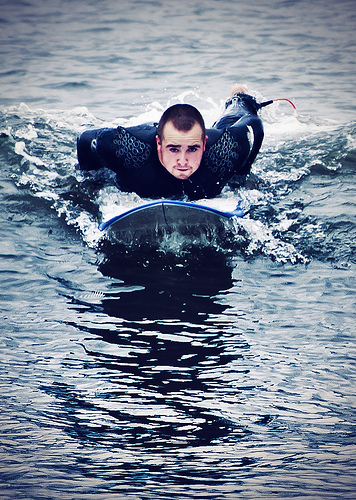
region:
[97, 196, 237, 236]
the tip of a surfboard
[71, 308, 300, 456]
a shadow of a surfer in the water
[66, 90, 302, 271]
surfer laying on surfboard in water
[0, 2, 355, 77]
a body of water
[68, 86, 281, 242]
a man on a surfboard is using hands to splash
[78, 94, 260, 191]
a man wearing a wet suit on a surfboard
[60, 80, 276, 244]
a surfer on a surfboard is using feet to move in water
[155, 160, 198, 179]
a man with a beard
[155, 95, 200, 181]
a brown hair man on surfboard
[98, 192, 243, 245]
a blue surfboard tip in water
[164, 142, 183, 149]
Eyebrow is dark brown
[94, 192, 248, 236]
Surfboard is white with blue lining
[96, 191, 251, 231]
Lining of surfboard is blue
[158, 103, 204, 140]
Hair is dark brown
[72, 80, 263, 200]
Man lying on surfboard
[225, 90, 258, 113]
Bird logo on man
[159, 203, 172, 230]
Line down middle of bottom of surfboard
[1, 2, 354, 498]
Water is blue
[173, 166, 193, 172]
Mouth is closed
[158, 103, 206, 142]
Hair is short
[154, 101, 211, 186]
man has facial hair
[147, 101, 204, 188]
man has dark short hair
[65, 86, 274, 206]
man is wearing a combination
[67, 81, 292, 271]
man laying on surfboard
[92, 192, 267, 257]
surfboard is blue and silver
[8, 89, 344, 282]
man is making waves in water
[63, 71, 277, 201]
man is looking on front of him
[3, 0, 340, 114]
water is calm with small waves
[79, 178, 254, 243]
surfboards has groove in the middle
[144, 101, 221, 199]
man has thick eyebrows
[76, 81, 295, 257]
a man riding a surfboard.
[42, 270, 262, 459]
a human reflection in the water.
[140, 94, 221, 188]
a man with short hair.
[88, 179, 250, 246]
a man on top of a surfboard.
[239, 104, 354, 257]
waves in the water.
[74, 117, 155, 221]
a man's right arm.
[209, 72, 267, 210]
a man's left arm.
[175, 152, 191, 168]
a nose on a man.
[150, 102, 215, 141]
hair on a human head.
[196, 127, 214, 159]
a man's left ear.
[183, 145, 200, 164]
left eye of surfer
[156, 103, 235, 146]
hair of the surfer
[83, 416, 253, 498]
blue waters in front of surfer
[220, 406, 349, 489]
ripples of the water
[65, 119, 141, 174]
right arm of surfer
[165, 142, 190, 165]
right eye of surfer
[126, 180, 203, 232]
tip of blue board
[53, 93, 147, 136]
white waves behind surfer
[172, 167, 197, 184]
chin of the surfer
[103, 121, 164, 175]
design on surf suit